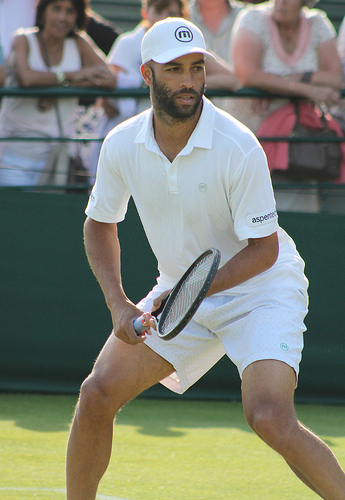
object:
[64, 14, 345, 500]
man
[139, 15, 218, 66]
hat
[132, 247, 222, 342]
racket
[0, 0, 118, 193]
woman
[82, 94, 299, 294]
shirt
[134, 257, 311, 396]
shorts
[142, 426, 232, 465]
court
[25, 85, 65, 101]
rail